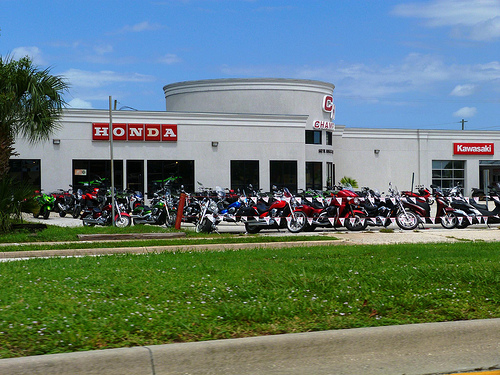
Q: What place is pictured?
A: It is a street.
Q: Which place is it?
A: It is a street.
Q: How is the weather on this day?
A: It is clear.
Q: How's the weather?
A: It is clear.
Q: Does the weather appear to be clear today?
A: Yes, it is clear.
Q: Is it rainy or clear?
A: It is clear.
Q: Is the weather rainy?
A: No, it is clear.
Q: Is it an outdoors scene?
A: Yes, it is outdoors.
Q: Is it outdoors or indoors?
A: It is outdoors.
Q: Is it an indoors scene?
A: No, it is outdoors.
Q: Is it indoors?
A: No, it is outdoors.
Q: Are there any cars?
A: No, there are no cars.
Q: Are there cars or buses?
A: No, there are no cars or buses.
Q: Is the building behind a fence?
A: No, the building is behind a bike.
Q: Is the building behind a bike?
A: Yes, the building is behind a bike.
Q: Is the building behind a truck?
A: No, the building is behind a bike.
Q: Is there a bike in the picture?
A: Yes, there is a bike.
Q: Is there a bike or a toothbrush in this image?
A: Yes, there is a bike.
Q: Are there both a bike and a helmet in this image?
A: No, there is a bike but no helmets.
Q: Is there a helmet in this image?
A: No, there are no helmets.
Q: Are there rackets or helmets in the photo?
A: No, there are no helmets or rackets.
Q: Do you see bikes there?
A: Yes, there is a bike.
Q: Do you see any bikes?
A: Yes, there is a bike.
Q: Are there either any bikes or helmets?
A: Yes, there is a bike.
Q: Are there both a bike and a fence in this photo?
A: No, there is a bike but no fences.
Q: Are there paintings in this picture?
A: No, there are no paintings.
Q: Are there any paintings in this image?
A: No, there are no paintings.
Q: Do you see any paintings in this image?
A: No, there are no paintings.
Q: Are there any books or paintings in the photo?
A: No, there are no paintings or books.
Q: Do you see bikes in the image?
A: Yes, there is a bike.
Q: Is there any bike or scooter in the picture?
A: Yes, there is a bike.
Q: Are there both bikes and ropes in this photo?
A: No, there is a bike but no ropes.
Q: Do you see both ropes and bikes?
A: No, there is a bike but no ropes.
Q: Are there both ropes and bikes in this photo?
A: No, there is a bike but no ropes.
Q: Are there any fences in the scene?
A: No, there are no fences.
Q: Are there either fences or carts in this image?
A: No, there are no fences or carts.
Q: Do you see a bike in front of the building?
A: Yes, there is a bike in front of the building.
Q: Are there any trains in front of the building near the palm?
A: No, there is a bike in front of the building.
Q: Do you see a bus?
A: No, there are no buses.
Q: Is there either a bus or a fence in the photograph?
A: No, there are no buses or fences.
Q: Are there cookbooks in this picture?
A: No, there are no cookbooks.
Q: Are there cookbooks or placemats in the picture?
A: No, there are no cookbooks or placemats.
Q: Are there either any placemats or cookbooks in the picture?
A: No, there are no cookbooks or placemats.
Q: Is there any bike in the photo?
A: Yes, there is a bike.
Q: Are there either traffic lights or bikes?
A: Yes, there is a bike.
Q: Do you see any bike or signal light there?
A: Yes, there is a bike.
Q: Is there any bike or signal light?
A: Yes, there is a bike.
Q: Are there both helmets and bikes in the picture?
A: No, there is a bike but no helmets.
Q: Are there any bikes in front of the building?
A: Yes, there is a bike in front of the building.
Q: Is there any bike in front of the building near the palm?
A: Yes, there is a bike in front of the building.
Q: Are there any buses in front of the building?
A: No, there is a bike in front of the building.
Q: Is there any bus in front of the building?
A: No, there is a bike in front of the building.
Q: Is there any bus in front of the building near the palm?
A: No, there is a bike in front of the building.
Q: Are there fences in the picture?
A: No, there are no fences.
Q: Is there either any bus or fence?
A: No, there are no fences or buses.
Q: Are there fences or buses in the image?
A: No, there are no fences or buses.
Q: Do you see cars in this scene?
A: No, there are no cars.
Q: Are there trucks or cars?
A: No, there are no cars or trucks.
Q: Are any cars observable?
A: No, there are no cars.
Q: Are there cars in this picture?
A: No, there are no cars.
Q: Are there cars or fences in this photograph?
A: No, there are no cars or fences.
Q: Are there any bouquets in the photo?
A: No, there are no bouquets.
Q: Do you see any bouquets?
A: No, there are no bouquets.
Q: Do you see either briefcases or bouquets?
A: No, there are no bouquets or briefcases.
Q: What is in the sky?
A: The clouds are in the sky.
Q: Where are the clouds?
A: The clouds are in the sky.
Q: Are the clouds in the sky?
A: Yes, the clouds are in the sky.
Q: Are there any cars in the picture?
A: No, there are no cars.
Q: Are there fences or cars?
A: No, there are no cars or fences.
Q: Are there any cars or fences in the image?
A: No, there are no cars or fences.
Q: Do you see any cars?
A: No, there are no cars.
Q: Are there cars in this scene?
A: No, there are no cars.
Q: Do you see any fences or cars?
A: No, there are no cars or fences.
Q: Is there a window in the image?
A: Yes, there is a window.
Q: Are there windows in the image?
A: Yes, there is a window.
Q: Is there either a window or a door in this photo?
A: Yes, there is a window.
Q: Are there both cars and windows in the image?
A: No, there is a window but no cars.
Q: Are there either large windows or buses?
A: Yes, there is a large window.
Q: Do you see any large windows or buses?
A: Yes, there is a large window.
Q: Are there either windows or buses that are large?
A: Yes, the window is large.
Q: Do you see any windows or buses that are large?
A: Yes, the window is large.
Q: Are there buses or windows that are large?
A: Yes, the window is large.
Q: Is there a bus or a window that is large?
A: Yes, the window is large.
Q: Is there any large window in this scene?
A: Yes, there is a large window.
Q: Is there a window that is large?
A: Yes, there is a window that is large.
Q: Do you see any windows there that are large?
A: Yes, there is a window that is large.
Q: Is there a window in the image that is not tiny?
A: Yes, there is a large window.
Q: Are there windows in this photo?
A: Yes, there is a window.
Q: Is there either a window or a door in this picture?
A: Yes, there is a window.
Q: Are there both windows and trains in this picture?
A: No, there is a window but no trains.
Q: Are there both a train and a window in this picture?
A: No, there is a window but no trains.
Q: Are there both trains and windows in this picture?
A: No, there is a window but no trains.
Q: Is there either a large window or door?
A: Yes, there is a large window.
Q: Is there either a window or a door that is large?
A: Yes, the window is large.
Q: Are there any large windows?
A: Yes, there is a large window.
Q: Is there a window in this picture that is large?
A: Yes, there is a window that is large.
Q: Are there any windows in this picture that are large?
A: Yes, there is a window that is large.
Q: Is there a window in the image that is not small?
A: Yes, there is a large window.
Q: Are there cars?
A: No, there are no cars.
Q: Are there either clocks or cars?
A: No, there are no cars or clocks.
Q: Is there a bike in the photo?
A: Yes, there is a bike.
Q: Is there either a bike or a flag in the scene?
A: Yes, there is a bike.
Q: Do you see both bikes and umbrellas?
A: No, there is a bike but no umbrellas.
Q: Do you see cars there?
A: No, there are no cars.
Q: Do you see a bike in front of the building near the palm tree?
A: Yes, there is a bike in front of the building.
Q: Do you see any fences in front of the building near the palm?
A: No, there is a bike in front of the building.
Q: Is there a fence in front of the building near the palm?
A: No, there is a bike in front of the building.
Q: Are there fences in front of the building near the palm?
A: No, there is a bike in front of the building.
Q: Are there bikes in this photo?
A: Yes, there is a bike.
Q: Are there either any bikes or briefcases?
A: Yes, there is a bike.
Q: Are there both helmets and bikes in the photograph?
A: No, there is a bike but no helmets.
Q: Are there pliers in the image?
A: No, there are no pliers.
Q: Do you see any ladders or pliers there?
A: No, there are no pliers or ladders.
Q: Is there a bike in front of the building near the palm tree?
A: Yes, there is a bike in front of the building.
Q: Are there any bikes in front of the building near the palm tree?
A: Yes, there is a bike in front of the building.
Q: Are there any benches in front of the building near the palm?
A: No, there is a bike in front of the building.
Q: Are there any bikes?
A: Yes, there is a bike.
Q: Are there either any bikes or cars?
A: Yes, there is a bike.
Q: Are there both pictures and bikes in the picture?
A: No, there is a bike but no pictures.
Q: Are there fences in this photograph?
A: No, there are no fences.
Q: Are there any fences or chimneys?
A: No, there are no fences or chimneys.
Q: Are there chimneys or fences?
A: No, there are no fences or chimneys.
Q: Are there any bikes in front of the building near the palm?
A: Yes, there is a bike in front of the building.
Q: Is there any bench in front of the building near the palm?
A: No, there is a bike in front of the building.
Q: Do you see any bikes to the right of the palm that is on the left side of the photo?
A: Yes, there is a bike to the right of the palm.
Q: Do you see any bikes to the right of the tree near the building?
A: Yes, there is a bike to the right of the palm.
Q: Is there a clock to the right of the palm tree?
A: No, there is a bike to the right of the palm tree.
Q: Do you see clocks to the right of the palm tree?
A: No, there is a bike to the right of the palm tree.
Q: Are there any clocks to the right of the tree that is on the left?
A: No, there is a bike to the right of the palm tree.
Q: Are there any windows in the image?
A: Yes, there is a window.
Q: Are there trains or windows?
A: Yes, there is a window.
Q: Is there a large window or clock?
A: Yes, there is a large window.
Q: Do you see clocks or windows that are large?
A: Yes, the window is large.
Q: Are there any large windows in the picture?
A: Yes, there is a large window.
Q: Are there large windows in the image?
A: Yes, there is a large window.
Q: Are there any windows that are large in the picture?
A: Yes, there is a large window.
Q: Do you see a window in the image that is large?
A: Yes, there is a window that is large.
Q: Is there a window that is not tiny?
A: Yes, there is a large window.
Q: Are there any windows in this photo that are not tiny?
A: Yes, there is a large window.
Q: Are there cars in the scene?
A: No, there are no cars.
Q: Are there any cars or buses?
A: No, there are no cars or buses.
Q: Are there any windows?
A: Yes, there is a window.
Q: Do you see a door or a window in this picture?
A: Yes, there is a window.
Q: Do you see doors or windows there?
A: Yes, there is a window.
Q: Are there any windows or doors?
A: Yes, there is a window.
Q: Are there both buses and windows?
A: No, there is a window but no buses.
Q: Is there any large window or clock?
A: Yes, there is a large window.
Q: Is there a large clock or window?
A: Yes, there is a large window.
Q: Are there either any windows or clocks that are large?
A: Yes, the window is large.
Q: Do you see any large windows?
A: Yes, there is a large window.